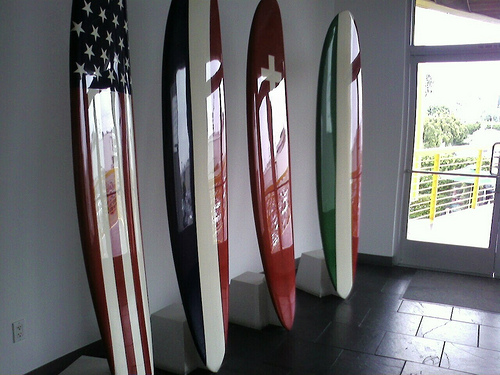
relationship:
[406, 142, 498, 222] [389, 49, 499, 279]
guard rail outside doorway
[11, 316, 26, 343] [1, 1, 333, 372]
electrical outlet on wall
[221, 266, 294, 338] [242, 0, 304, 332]
box holding up surfboard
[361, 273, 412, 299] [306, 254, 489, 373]
tile on floor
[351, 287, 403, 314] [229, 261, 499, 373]
tile on floor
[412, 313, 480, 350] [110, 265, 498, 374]
tile on floor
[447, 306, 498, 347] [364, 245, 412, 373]
tile on floor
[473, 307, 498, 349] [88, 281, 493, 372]
tile on floor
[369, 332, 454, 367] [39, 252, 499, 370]
grey tile on floor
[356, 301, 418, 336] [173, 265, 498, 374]
tile on floor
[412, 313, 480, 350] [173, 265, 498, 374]
tile on floor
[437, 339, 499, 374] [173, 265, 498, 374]
tile on floor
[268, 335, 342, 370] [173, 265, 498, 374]
tile on floor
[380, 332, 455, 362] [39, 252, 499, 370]
grey tile on floor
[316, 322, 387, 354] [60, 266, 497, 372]
tile on floor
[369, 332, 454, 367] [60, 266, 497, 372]
grey tile on floor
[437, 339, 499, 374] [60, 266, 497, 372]
tile on floor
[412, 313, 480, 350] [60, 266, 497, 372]
tile on floor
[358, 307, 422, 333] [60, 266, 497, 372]
tile on floor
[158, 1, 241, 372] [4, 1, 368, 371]
surfboard against wall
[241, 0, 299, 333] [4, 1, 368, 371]
surf boards against wall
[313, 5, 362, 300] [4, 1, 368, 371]
surfboard against wall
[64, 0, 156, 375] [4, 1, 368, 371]
surf board against wall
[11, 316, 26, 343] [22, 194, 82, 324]
electrical outlet on wall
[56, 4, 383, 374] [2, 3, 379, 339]
surf boards against wall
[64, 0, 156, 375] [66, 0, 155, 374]
surf board on left has american flag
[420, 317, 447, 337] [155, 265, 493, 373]
crack in one of tiles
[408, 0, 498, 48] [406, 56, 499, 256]
window over door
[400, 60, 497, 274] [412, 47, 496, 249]
door made of glass door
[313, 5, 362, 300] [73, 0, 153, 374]
surfboard with an american flag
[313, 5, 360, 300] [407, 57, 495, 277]
surfboard beside door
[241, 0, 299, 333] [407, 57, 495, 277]
surf boards beside door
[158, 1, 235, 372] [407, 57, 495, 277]
surfboard beside door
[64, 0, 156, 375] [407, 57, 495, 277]
surf board beside door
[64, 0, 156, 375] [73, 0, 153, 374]
surf board with american flag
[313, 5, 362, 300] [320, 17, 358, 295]
surfboard with graphic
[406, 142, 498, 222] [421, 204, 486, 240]
guard rail across cement surface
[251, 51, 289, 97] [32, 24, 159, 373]
cross design on surfboard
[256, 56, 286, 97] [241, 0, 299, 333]
cross on surf boards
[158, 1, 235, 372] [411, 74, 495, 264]
surfboard reflect outdoors